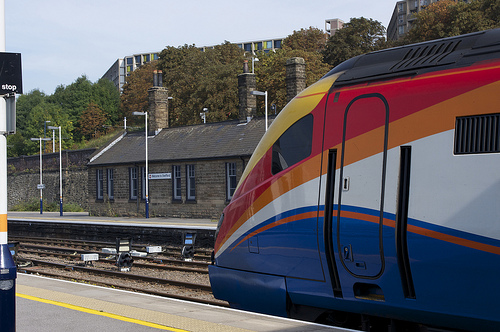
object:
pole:
[144, 163, 148, 270]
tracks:
[0, 265, 228, 308]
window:
[265, 113, 314, 175]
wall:
[0, 153, 89, 216]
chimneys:
[145, 67, 170, 131]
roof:
[82, 118, 270, 164]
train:
[208, 25, 500, 328]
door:
[337, 92, 389, 280]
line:
[15, 292, 186, 332]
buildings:
[100, 19, 343, 95]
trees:
[157, 41, 243, 120]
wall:
[90, 158, 236, 217]